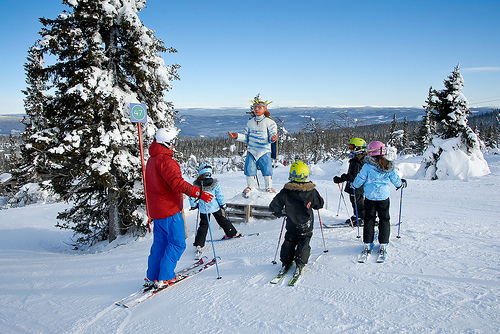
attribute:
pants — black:
[362, 197, 388, 242]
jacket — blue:
[334, 146, 455, 263]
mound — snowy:
[0, 143, 497, 331]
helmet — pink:
[365, 135, 382, 160]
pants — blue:
[141, 213, 186, 280]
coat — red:
[145, 141, 202, 219]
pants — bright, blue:
[141, 207, 186, 284]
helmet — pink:
[354, 136, 400, 163]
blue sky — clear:
[275, 28, 359, 80]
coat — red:
[140, 140, 197, 221]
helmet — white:
[152, 123, 177, 143]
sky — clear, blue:
[213, 34, 380, 80]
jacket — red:
[136, 145, 209, 218]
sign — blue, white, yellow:
[101, 99, 202, 153]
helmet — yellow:
[288, 161, 309, 181]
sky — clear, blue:
[176, 14, 435, 99]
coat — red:
[137, 143, 209, 222]